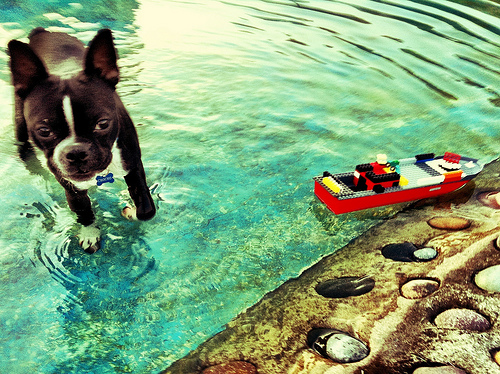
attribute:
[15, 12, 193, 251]
dog — blue, head, foot, food, eye, black, looking, standing, pair, bone, reflection, white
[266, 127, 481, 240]
boat — toy, lego, tip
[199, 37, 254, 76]
light — reflection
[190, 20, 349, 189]
water — clear, body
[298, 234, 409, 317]
rock — cement, embedded, oval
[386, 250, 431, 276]
stone — small